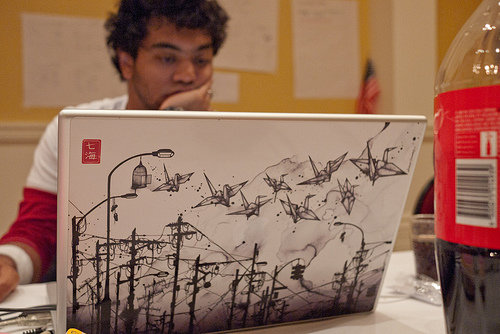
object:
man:
[0, 1, 231, 301]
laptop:
[52, 110, 432, 334]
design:
[65, 122, 424, 331]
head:
[103, 0, 233, 109]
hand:
[160, 80, 214, 111]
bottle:
[431, 0, 499, 333]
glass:
[408, 214, 439, 291]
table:
[0, 247, 448, 334]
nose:
[172, 62, 196, 84]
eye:
[156, 53, 177, 64]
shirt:
[0, 94, 130, 284]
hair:
[103, 1, 232, 81]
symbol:
[82, 139, 102, 165]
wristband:
[1, 242, 34, 284]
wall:
[2, 1, 499, 215]